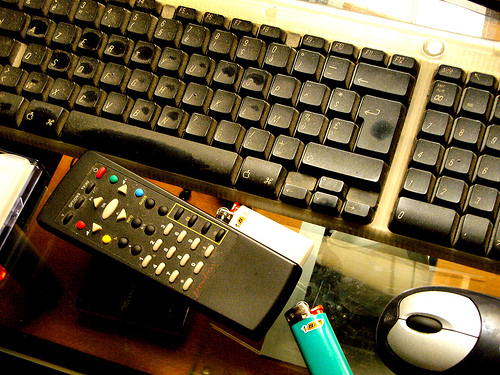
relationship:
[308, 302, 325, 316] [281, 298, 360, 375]
button on lighter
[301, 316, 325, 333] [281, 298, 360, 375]
logo on lighter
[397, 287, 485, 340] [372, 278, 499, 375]
button on mouse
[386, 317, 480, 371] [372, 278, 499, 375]
button on mouse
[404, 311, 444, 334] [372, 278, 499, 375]
wheel on mouse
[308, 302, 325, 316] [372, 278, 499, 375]
button on mouse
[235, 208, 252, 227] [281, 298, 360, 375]
logo on lighter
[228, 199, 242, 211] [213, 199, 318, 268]
button on lighter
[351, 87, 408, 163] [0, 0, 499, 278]
key on keyboard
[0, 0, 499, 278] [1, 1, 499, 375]
keyboard on desk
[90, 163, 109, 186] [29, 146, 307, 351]
button on remote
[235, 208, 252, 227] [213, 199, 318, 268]
logo on lighter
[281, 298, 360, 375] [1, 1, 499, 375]
lighter on desk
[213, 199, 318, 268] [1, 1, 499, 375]
lighter on desk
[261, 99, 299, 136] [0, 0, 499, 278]
key on keyboard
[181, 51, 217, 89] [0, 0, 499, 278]
key on keyboard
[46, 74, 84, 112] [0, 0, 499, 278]
key on keyboard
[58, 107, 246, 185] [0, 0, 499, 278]
spacebar on keyboard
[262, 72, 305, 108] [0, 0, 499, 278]
key on keyboard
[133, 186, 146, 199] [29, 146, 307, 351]
button on remote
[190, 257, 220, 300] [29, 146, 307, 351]
print on remote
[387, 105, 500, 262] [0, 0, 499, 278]
pad on keyboard